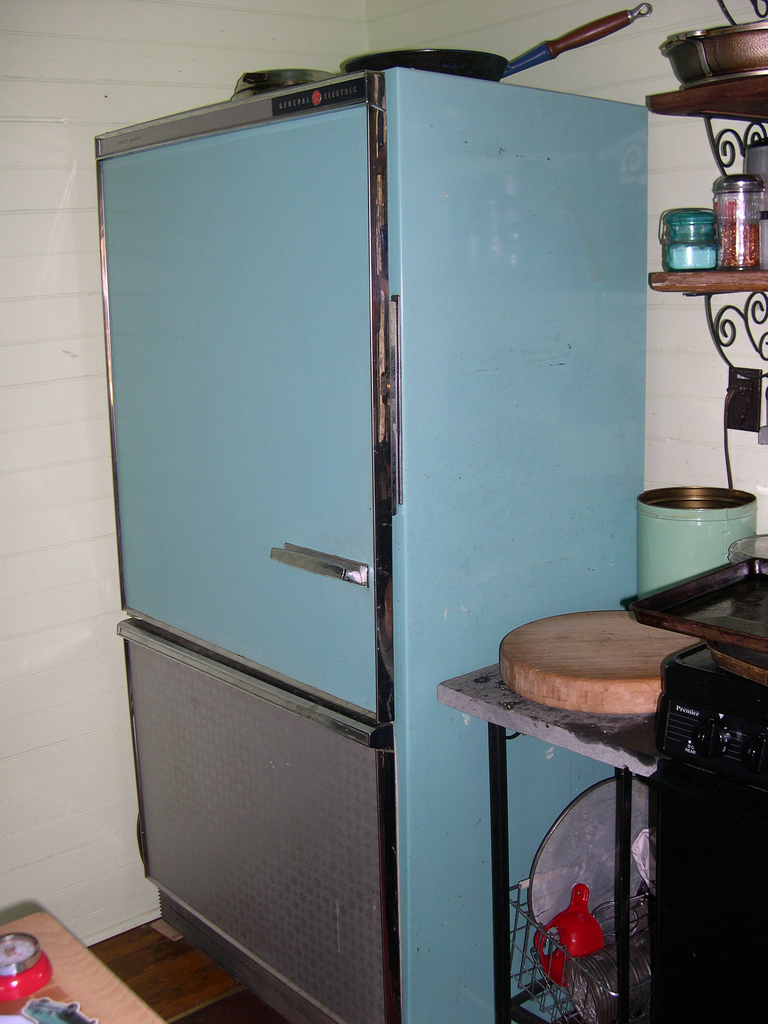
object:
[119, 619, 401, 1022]
freezer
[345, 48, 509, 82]
skillet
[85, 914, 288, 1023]
floor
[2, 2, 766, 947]
wall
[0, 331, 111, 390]
tile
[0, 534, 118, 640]
tile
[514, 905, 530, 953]
iron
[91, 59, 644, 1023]
fridge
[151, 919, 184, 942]
stone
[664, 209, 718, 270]
box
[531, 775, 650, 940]
plate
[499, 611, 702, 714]
tray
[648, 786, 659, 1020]
leg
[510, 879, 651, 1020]
basket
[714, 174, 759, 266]
bottle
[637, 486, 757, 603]
jar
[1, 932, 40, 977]
clock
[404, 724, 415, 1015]
line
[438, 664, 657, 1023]
table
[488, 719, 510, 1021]
leg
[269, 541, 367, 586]
handle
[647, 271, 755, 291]
shelf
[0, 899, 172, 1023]
table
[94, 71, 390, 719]
drawer